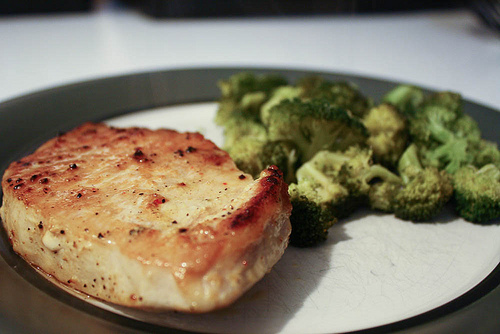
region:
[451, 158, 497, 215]
Green veggie on plate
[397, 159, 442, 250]
Green veggie on plate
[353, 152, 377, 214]
Green veggie on plate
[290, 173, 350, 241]
Green veggie on plate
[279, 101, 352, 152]
Green veggie on plate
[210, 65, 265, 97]
Green veggie on plate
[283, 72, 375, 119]
Green veggie on plate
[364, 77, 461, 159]
Green veggie on plate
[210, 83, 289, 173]
Green veggie on plate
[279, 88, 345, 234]
Green veggie on plate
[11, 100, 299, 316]
a baked piece of fish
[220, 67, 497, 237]
steamed broccoli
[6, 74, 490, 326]
the plate is round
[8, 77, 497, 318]
a plate of hot food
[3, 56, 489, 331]
a plate of cooked food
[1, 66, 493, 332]
baked fish with a side of steamed broccoli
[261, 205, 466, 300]
scratch marks on the plate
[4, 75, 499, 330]
the plate is white and grey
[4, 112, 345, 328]
the fish is seasoned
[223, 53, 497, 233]
steamed broccoli florets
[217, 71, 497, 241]
Cooked brocolli on plate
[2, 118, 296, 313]
Cooked meat on plate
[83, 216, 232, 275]
Moisture marks on cooked meat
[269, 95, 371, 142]
Crown of brocolli floret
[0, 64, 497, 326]
Black rim of dinner plate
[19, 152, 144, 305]
Black seasoning marks on meat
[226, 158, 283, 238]
Burn marks on meat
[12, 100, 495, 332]
White inner ring of dinner plate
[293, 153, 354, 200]
Piece of brocolli stem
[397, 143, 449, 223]
Cooked brocolli floret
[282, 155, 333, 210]
green food on plate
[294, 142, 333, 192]
green food on plate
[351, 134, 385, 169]
green food on plate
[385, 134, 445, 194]
green food on plate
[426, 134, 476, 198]
green food on plate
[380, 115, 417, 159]
green food on plate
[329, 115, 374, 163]
green food on plate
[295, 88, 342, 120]
green food on plate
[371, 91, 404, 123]
green food on plate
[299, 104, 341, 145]
green food on plate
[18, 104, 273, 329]
the meat is grilled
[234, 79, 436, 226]
the broccoli is dry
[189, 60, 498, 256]
the broccoli is dry